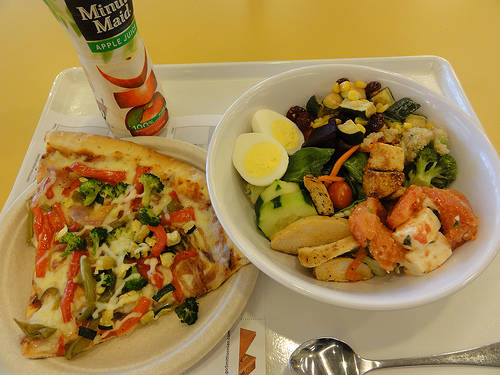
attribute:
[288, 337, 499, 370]
spoon — silver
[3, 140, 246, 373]
plate — white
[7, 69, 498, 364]
tray — white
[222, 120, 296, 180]
eggs — cut, yellow, white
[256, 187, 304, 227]
cucumber — sliced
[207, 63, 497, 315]
plate — white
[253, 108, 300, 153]
egg — boiled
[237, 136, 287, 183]
egg — boiled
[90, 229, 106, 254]
broccoli — green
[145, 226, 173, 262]
peppers — red, green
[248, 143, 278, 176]
yolk — yellow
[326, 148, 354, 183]
carrots — shredded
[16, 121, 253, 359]
food — vegetarian, large